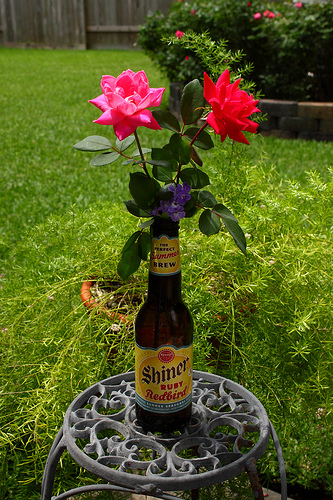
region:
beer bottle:
[128, 227, 200, 411]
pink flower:
[102, 68, 150, 120]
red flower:
[196, 55, 261, 156]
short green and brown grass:
[2, 48, 48, 89]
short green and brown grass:
[10, 101, 47, 143]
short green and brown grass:
[17, 178, 48, 219]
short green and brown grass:
[10, 198, 44, 261]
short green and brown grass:
[31, 197, 74, 230]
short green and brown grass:
[250, 165, 291, 215]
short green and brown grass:
[265, 201, 317, 270]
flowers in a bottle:
[73, 44, 231, 318]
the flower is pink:
[99, 68, 195, 196]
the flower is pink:
[158, 35, 260, 236]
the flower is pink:
[63, 36, 187, 231]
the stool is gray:
[63, 390, 128, 451]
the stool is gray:
[191, 416, 269, 494]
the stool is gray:
[92, 382, 185, 483]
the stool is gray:
[215, 369, 270, 466]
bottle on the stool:
[117, 214, 240, 453]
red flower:
[83, 69, 155, 177]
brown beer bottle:
[115, 208, 202, 425]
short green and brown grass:
[17, 207, 65, 250]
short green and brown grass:
[237, 289, 266, 317]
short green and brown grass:
[262, 199, 296, 238]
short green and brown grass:
[253, 156, 291, 177]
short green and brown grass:
[17, 156, 42, 189]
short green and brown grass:
[19, 62, 68, 105]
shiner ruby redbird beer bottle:
[134, 218, 193, 425]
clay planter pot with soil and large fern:
[78, 253, 202, 331]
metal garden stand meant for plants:
[39, 365, 290, 499]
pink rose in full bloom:
[94, 68, 161, 141]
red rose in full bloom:
[200, 67, 258, 141]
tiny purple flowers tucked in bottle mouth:
[157, 183, 195, 222]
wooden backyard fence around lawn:
[3, 0, 149, 54]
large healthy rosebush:
[147, 0, 331, 97]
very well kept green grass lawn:
[0, 61, 332, 274]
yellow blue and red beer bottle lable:
[136, 346, 194, 412]